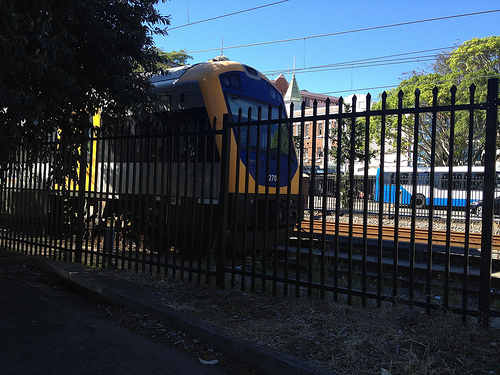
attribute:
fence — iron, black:
[106, 72, 487, 322]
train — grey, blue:
[1, 47, 302, 274]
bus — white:
[365, 151, 496, 219]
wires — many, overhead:
[319, 27, 406, 95]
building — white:
[242, 75, 404, 174]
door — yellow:
[37, 72, 111, 218]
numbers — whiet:
[247, 167, 292, 205]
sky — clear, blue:
[238, 9, 318, 44]